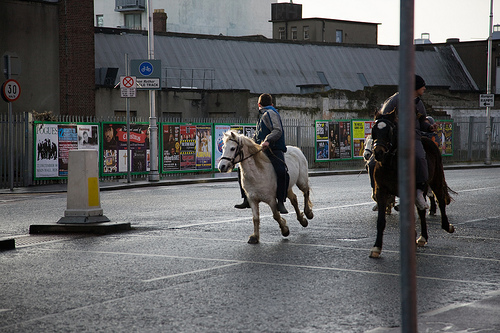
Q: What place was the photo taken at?
A: It was taken at the road.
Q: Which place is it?
A: It is a road.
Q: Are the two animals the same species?
A: Yes, all the animals are horses.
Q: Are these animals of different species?
A: No, all the animals are horses.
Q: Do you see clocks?
A: No, there are no clocks.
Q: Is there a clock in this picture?
A: No, there are no clocks.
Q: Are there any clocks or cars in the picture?
A: No, there are no clocks or cars.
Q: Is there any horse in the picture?
A: Yes, there is a horse.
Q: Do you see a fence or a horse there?
A: Yes, there is a horse.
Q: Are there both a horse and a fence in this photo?
A: Yes, there are both a horse and a fence.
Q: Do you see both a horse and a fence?
A: Yes, there are both a horse and a fence.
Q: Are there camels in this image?
A: No, there are no camels.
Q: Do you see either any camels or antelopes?
A: No, there are no camels or antelopes.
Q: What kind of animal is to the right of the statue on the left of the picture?
A: The animal is a horse.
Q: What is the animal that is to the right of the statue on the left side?
A: The animal is a horse.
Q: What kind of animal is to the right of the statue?
A: The animal is a horse.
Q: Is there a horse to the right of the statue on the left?
A: Yes, there is a horse to the right of the statue.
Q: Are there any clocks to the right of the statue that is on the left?
A: No, there is a horse to the right of the statue.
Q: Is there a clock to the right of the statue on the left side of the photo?
A: No, there is a horse to the right of the statue.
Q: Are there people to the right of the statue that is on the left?
A: Yes, there is a person to the right of the statue.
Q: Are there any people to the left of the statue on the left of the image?
A: No, the person is to the right of the statue.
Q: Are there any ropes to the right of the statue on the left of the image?
A: No, there is a person to the right of the statue.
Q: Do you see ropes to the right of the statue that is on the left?
A: No, there is a person to the right of the statue.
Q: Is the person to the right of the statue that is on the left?
A: Yes, the person is to the right of the statue.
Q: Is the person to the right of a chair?
A: No, the person is to the right of the statue.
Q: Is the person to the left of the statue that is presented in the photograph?
A: No, the person is to the right of the statue.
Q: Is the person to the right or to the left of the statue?
A: The person is to the right of the statue.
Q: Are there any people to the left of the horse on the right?
A: Yes, there is a person to the left of the horse.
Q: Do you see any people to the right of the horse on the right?
A: No, the person is to the left of the horse.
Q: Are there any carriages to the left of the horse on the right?
A: No, there is a person to the left of the horse.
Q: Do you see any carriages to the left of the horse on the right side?
A: No, there is a person to the left of the horse.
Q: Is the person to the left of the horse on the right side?
A: Yes, the person is to the left of the horse.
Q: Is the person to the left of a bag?
A: No, the person is to the left of the horse.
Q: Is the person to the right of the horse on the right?
A: No, the person is to the left of the horse.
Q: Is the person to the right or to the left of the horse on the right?
A: The person is to the left of the horse.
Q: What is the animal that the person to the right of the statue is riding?
A: The animal is a horse.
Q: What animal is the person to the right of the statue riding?
A: The person is riding a horse.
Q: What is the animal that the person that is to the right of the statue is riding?
A: The animal is a horse.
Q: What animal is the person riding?
A: The person is riding a horse.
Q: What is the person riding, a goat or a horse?
A: The person is riding a horse.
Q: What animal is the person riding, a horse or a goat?
A: The person is riding a horse.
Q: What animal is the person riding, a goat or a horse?
A: The person is riding a horse.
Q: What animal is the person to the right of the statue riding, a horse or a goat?
A: The person is riding a horse.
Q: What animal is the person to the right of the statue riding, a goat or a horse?
A: The person is riding a horse.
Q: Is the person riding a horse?
A: Yes, the person is riding a horse.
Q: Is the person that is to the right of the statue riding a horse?
A: Yes, the person is riding a horse.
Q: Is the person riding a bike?
A: No, the person is riding a horse.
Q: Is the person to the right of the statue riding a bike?
A: No, the person is riding a horse.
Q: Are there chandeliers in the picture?
A: No, there are no chandeliers.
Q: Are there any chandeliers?
A: No, there are no chandeliers.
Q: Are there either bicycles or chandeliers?
A: No, there are no chandeliers or bicycles.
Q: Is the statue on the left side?
A: Yes, the statue is on the left of the image.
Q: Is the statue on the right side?
A: No, the statue is on the left of the image.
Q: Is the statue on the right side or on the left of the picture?
A: The statue is on the left of the image.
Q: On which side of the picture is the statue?
A: The statue is on the left of the image.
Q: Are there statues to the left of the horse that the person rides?
A: Yes, there is a statue to the left of the horse.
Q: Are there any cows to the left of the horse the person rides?
A: No, there is a statue to the left of the horse.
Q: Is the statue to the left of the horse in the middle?
A: Yes, the statue is to the left of the horse.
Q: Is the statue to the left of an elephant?
A: No, the statue is to the left of the horse.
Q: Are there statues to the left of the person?
A: Yes, there is a statue to the left of the person.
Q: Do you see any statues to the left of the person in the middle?
A: Yes, there is a statue to the left of the person.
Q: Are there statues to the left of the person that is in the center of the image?
A: Yes, there is a statue to the left of the person.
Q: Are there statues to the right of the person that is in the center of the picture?
A: No, the statue is to the left of the person.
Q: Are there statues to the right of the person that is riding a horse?
A: No, the statue is to the left of the person.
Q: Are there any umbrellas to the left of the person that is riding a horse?
A: No, there is a statue to the left of the person.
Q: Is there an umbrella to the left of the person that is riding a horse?
A: No, there is a statue to the left of the person.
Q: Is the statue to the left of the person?
A: Yes, the statue is to the left of the person.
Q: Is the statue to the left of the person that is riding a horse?
A: Yes, the statue is to the left of the person.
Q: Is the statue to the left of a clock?
A: No, the statue is to the left of the person.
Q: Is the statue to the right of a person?
A: No, the statue is to the left of a person.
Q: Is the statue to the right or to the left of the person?
A: The statue is to the left of the person.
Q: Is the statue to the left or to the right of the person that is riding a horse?
A: The statue is to the left of the person.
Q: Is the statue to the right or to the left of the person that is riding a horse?
A: The statue is to the left of the person.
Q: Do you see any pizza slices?
A: No, there are no pizza slices.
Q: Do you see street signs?
A: Yes, there is a street sign.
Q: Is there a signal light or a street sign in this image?
A: Yes, there is a street sign.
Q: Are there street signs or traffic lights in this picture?
A: Yes, there is a street sign.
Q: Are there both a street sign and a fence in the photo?
A: Yes, there are both a street sign and a fence.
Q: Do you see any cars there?
A: No, there are no cars.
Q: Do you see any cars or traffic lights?
A: No, there are no cars or traffic lights.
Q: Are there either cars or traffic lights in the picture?
A: No, there are no cars or traffic lights.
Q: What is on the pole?
A: The street sign is on the pole.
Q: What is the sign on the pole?
A: The sign is a street sign.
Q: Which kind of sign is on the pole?
A: The sign is a street sign.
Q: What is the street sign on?
A: The street sign is on the pole.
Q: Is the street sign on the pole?
A: Yes, the street sign is on the pole.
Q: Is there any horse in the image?
A: Yes, there is a horse.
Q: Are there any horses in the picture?
A: Yes, there is a horse.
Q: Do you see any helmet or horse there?
A: Yes, there is a horse.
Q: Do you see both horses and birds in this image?
A: No, there is a horse but no birds.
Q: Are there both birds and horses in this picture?
A: No, there is a horse but no birds.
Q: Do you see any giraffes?
A: No, there are no giraffes.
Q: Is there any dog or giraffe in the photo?
A: No, there are no giraffes or dogs.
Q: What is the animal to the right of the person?
A: The animal is a horse.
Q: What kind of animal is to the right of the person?
A: The animal is a horse.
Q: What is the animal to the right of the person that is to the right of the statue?
A: The animal is a horse.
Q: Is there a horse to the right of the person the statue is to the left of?
A: Yes, there is a horse to the right of the person.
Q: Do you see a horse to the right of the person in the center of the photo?
A: Yes, there is a horse to the right of the person.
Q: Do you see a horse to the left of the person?
A: No, the horse is to the right of the person.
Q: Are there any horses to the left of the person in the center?
A: No, the horse is to the right of the person.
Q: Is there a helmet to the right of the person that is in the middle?
A: No, there is a horse to the right of the person.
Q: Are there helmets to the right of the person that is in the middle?
A: No, there is a horse to the right of the person.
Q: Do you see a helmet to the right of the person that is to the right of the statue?
A: No, there is a horse to the right of the person.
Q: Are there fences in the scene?
A: Yes, there is a fence.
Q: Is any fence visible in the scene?
A: Yes, there is a fence.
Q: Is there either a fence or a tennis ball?
A: Yes, there is a fence.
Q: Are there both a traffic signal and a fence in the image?
A: No, there is a fence but no traffic lights.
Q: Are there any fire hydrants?
A: No, there are no fire hydrants.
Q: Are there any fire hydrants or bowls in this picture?
A: No, there are no fire hydrants or bowls.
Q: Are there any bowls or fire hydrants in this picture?
A: No, there are no fire hydrants or bowls.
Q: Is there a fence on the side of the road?
A: Yes, there is a fence on the side of the road.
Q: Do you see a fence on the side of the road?
A: Yes, there is a fence on the side of the road.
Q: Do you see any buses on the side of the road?
A: No, there is a fence on the side of the road.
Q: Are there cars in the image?
A: No, there are no cars.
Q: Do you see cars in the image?
A: No, there are no cars.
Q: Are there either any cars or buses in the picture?
A: No, there are no cars or buses.